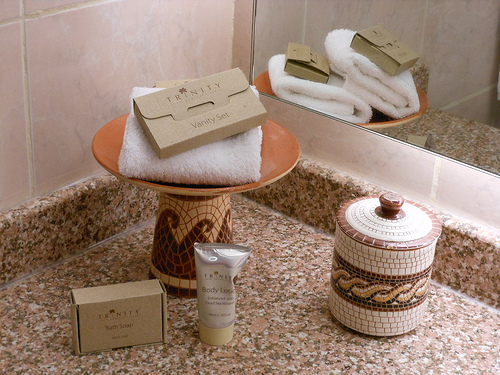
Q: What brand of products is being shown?
A: Trinity.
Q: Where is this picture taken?
A: Bathroom.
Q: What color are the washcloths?
A: White.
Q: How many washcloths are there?
A: Two.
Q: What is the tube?
A: Body lotion.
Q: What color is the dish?
A: Orange.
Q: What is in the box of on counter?
A: Soap.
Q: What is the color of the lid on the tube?
A: Yellow.